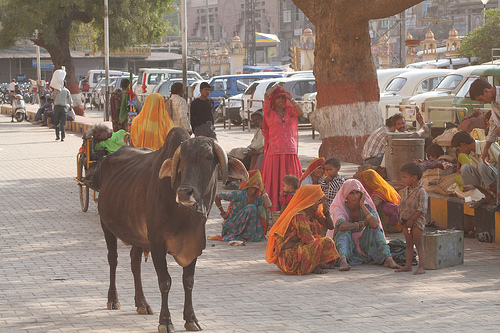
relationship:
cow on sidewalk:
[23, 90, 232, 329] [230, 285, 380, 330]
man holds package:
[54, 91, 72, 142] [60, 105, 72, 126]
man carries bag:
[54, 91, 72, 142] [52, 60, 64, 92]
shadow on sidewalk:
[17, 163, 99, 330] [230, 285, 380, 330]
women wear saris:
[240, 139, 402, 284] [274, 186, 372, 229]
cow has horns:
[23, 90, 232, 329] [165, 129, 237, 190]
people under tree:
[191, 61, 484, 257] [295, 5, 427, 181]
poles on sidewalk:
[33, 11, 191, 122] [230, 285, 380, 330]